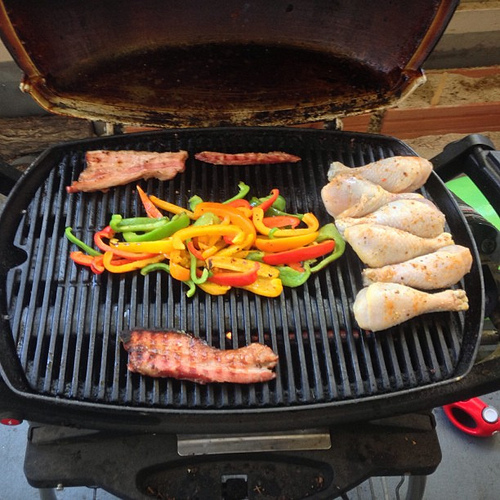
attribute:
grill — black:
[4, 129, 494, 493]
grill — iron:
[0, 128, 498, 434]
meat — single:
[88, 290, 346, 374]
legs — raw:
[319, 150, 473, 333]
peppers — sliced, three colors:
[66, 177, 348, 298]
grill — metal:
[0, 4, 500, 497]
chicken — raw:
[346, 159, 433, 188]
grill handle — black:
[2, 158, 25, 422]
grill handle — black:
[427, 133, 499, 216]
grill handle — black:
[465, 335, 497, 398]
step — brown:
[419, 102, 491, 140]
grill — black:
[11, 277, 118, 386]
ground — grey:
[427, 106, 457, 140]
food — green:
[65, 226, 104, 256]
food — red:
[72, 196, 349, 305]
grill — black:
[0, 125, 499, 405]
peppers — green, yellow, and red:
[80, 180, 339, 298]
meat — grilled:
[314, 147, 474, 336]